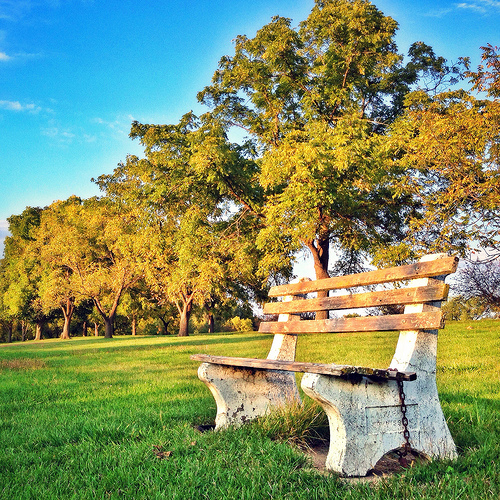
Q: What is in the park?
A: Bench.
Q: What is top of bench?
A: Wood.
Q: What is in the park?
A: Trees.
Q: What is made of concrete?
A: The legs of a bench.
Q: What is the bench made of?
A: Wood and concrete.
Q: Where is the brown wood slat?
A: On a bench.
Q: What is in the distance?
A: A large green tree.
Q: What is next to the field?
A: A large green tree.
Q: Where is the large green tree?
A: The tree is in the distance.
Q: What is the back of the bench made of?
A: The back of the bench is wood.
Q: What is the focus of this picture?
A: A bench.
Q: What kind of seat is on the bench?
A: Wooden.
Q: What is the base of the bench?
A: Cement.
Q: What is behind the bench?
A: Trees.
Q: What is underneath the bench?
A: Grass.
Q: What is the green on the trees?
A: Leaves.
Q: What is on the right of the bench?
A: A chain.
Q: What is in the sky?
A: Clouds.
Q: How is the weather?
A: Sunny.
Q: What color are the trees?
A: Green.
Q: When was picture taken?
A: Daytime.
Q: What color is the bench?
A: Brown.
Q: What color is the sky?
A: Blue.